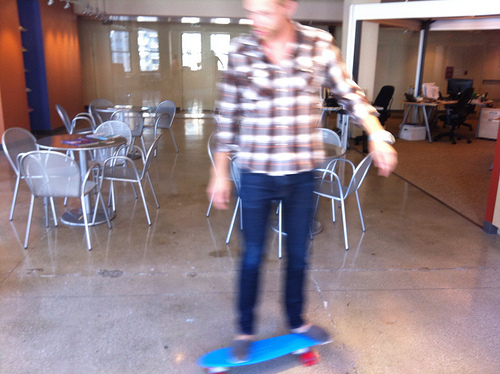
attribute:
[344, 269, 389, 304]
tile — tan, square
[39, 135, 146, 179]
table — round, silver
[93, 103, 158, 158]
table — metal, round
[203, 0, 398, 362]
man — blurry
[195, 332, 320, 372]
skateboard — blue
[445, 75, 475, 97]
monitor — dark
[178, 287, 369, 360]
skateboard — blue, bright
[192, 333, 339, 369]
skateboard — blue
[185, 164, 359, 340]
jeans — blue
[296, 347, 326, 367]
wheel — red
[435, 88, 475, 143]
chair — black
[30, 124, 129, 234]
table — round, metal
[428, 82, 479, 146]
office chair — black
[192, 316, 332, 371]
skateboard — bright, blue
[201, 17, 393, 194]
shirt — brown, white, checkered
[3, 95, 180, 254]
chairs — empty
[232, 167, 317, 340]
table — round, metal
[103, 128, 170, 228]
chair — silver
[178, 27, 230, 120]
door — white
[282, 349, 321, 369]
wheels — red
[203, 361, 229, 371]
wheels — red